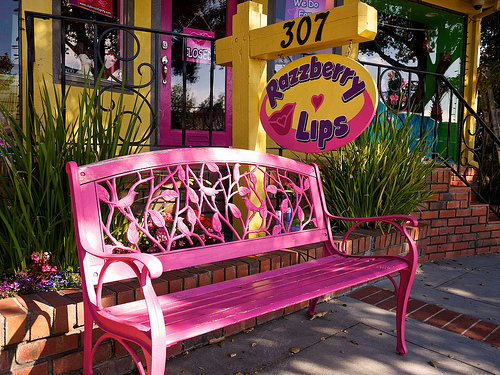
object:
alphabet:
[293, 110, 350, 149]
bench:
[65, 146, 420, 375]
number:
[280, 11, 329, 50]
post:
[213, 0, 378, 254]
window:
[171, 19, 225, 130]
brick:
[349, 280, 499, 351]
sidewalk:
[184, 276, 489, 374]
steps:
[437, 151, 495, 248]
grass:
[0, 106, 143, 278]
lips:
[267, 102, 295, 135]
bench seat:
[85, 252, 429, 348]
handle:
[161, 56, 168, 85]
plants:
[331, 80, 446, 215]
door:
[165, 4, 228, 170]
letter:
[319, 113, 334, 150]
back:
[75, 147, 330, 287]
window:
[47, 8, 141, 85]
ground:
[64, 245, 499, 370]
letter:
[333, 115, 350, 137]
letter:
[295, 64, 308, 82]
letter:
[341, 75, 366, 100]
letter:
[294, 109, 310, 140]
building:
[4, 3, 496, 375]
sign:
[230, 5, 385, 240]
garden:
[4, 110, 412, 260]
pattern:
[94, 160, 323, 264]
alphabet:
[266, 78, 284, 108]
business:
[0, 0, 483, 178]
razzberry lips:
[269, 59, 366, 150]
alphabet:
[264, 55, 366, 150]